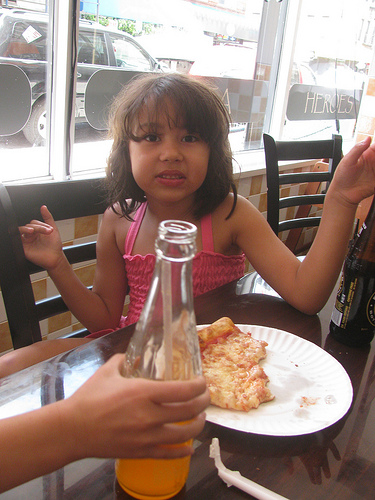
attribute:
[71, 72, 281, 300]
girl — sitting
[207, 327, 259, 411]
pizza — part, sliced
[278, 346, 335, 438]
plate — white, paper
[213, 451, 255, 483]
wrapper — white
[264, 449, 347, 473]
table — part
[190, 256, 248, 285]
dress — pink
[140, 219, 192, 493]
bottle — orange, brown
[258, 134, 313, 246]
chair — wooden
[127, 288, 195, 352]
glass — tall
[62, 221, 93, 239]
tile — colorful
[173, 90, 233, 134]
hair — brown, dark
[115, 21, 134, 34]
leaves — green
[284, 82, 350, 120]
sign — dark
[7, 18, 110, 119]
car — parked